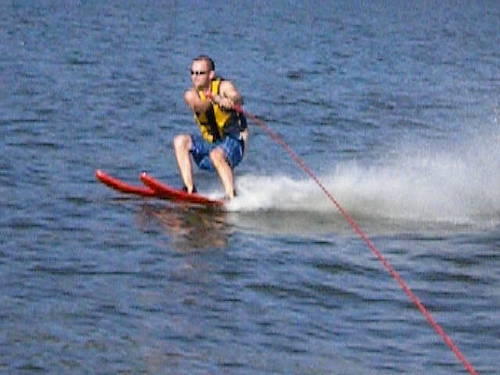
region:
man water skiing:
[0, 41, 116, 210]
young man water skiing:
[75, 56, 262, 213]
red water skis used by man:
[95, 168, 207, 217]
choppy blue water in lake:
[21, 20, 77, 68]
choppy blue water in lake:
[19, 80, 82, 128]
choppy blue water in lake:
[62, 96, 147, 155]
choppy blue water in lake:
[33, 228, 148, 314]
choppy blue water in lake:
[155, 227, 262, 345]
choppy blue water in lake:
[278, 254, 382, 334]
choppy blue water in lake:
[303, 41, 443, 149]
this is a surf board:
[80, 131, 222, 246]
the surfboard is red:
[84, 125, 226, 239]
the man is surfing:
[172, 43, 277, 205]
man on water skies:
[90, 2, 286, 252]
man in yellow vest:
[82, 42, 240, 252]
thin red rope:
[334, 206, 376, 260]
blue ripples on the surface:
[187, 265, 288, 336]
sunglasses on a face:
[177, 55, 219, 90]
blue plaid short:
[225, 137, 240, 158]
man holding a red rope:
[65, 42, 428, 349]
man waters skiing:
[70, 30, 268, 257]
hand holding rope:
[183, 91, 238, 118]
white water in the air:
[360, 137, 447, 204]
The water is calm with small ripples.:
[2, 0, 496, 373]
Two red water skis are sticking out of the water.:
[94, 166, 243, 206]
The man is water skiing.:
[93, 57, 250, 214]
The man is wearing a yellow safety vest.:
[195, 78, 234, 144]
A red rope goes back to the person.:
[233, 105, 473, 372]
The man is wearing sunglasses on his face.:
[190, 57, 215, 89]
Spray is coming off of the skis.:
[93, 126, 494, 237]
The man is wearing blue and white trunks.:
[190, 127, 249, 172]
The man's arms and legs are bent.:
[173, 86, 245, 200]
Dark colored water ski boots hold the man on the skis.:
[93, 167, 239, 212]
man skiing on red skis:
[167, 51, 249, 206]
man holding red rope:
[169, 52, 256, 212]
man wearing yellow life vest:
[173, 50, 255, 208]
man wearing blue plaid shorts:
[175, 51, 250, 197]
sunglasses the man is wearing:
[188, 65, 209, 76]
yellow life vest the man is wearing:
[187, 77, 244, 139]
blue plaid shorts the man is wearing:
[184, 119, 241, 172]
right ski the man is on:
[138, 166, 235, 213]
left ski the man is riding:
[89, 154, 172, 211]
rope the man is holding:
[202, 89, 483, 374]